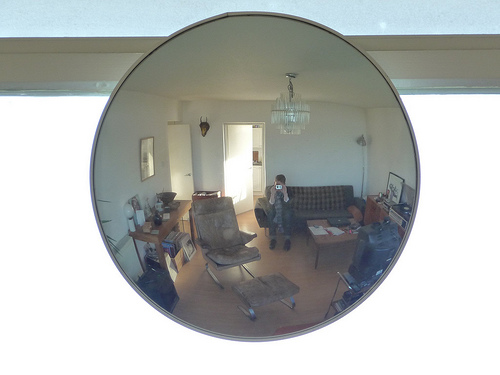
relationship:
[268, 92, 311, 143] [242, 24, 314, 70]
chandelier hanging from ceiling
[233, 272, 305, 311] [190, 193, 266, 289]
ottoman in front of a chair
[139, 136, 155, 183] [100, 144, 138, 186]
frame hanging on wall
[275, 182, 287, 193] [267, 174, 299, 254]
camera held by a person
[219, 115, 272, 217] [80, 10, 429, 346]
doorway in mirror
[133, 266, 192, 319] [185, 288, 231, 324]
suitcase on floor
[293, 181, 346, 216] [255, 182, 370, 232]
blanket on couch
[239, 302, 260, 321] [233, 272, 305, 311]
metal legs on an ottoman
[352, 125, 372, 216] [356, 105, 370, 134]
lamp in corner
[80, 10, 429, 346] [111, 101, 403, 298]
mirror showing room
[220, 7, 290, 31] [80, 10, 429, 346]
edge of a mirror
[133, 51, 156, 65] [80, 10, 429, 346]
part of a mirror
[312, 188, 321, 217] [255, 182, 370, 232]
part of a sofa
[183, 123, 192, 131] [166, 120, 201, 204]
edge of a door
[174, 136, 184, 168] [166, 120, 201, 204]
side of a door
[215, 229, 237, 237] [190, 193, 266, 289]
part of a chair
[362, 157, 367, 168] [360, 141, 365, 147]
part of a light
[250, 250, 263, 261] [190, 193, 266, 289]
edge of a seat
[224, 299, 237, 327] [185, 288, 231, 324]
part of a floor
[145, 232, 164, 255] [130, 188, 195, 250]
part of a table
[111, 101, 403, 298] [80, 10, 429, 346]
room reflected on mirror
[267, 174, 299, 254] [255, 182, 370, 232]
person sits on a couch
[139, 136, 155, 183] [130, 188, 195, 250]
frame of a table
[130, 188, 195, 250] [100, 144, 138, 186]
table against wall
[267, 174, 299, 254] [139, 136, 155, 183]
person taking a frame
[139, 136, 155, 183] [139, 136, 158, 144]
frame in a frame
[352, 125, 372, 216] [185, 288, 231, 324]
lamp on floor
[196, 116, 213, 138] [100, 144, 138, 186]
statue on wall